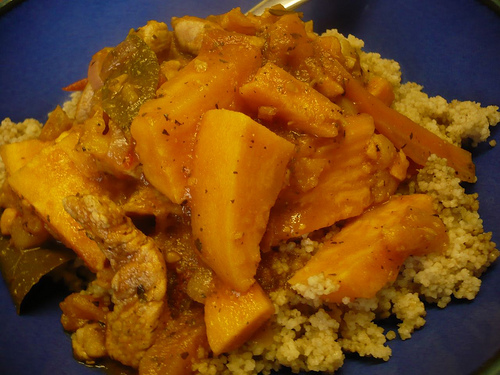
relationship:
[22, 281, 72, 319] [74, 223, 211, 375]
shadow from food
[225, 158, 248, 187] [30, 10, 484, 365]
grain prepared as a meal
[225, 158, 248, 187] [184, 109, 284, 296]
grain covered in vegetable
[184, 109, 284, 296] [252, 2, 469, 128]
vegetable sit on top of grain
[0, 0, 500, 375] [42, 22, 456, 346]
plate has food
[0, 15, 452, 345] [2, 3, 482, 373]
food on a plate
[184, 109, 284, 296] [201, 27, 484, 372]
vegetable on top of rice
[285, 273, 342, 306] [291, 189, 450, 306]
rice stuck to food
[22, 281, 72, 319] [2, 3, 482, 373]
shadow on plate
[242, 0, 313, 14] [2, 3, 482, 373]
handle on plate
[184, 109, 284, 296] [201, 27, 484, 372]
vegetable on rice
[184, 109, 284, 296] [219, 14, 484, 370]
vegetable covered in grain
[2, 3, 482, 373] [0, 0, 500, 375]
plate of food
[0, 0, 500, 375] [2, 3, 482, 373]
food on plate